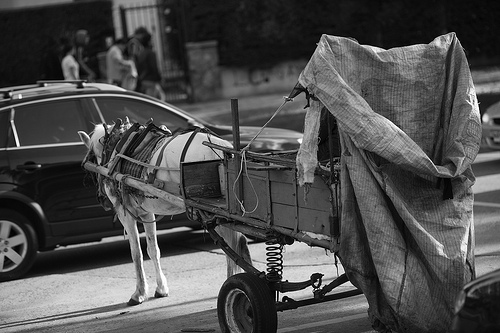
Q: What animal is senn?
A: Horse.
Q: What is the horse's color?
A: White.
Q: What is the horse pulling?
A: Cart.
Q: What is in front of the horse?
A: Car.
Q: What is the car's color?
A: Black.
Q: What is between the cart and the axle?
A: Spring.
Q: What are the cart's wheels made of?
A: Rubber.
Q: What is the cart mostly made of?
A: Wood.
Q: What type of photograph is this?
A: Black and white.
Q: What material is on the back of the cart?
A: Canvas.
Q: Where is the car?
A: In front of the horse?.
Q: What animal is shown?
A: A horse.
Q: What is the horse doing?
A: Pulling a cart.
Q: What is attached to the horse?
A: Cart.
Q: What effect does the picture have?
A: Black and white.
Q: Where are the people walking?
A: On the sidewalk.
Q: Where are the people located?
A: Background.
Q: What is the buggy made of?
A: Wood and sticks.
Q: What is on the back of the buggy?
A: Bag.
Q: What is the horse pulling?
A: Small cart.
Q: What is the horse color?
A: White.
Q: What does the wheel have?
A: Spring suspension.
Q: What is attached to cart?
A: Bag.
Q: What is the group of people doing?
A: Walking on sidewalk.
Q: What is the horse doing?
A: Standing in the street.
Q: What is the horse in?
A: Harness.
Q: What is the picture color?
A: Black and white.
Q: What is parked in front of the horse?
A: Car.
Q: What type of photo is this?
A: Black and white.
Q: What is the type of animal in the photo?
A: Donkey.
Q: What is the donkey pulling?
A: Cart.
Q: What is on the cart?
A: Wheels.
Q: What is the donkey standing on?
A: Road.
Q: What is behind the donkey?
A: Car.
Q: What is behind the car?
A: Men and women.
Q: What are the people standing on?
A: Sidewalk.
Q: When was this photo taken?
A: Daytime.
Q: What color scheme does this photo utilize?
A: Black and White.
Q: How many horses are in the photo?
A: One.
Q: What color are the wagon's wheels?
A: Black.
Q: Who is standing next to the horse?
A: No one.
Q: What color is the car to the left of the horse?
A: Black.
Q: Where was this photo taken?
A: On a street.